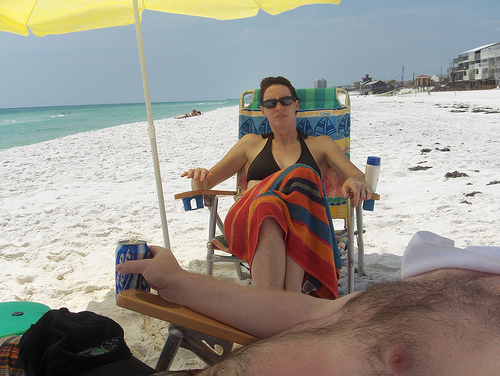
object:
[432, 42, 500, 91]
beach house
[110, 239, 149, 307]
can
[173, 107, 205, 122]
people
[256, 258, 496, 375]
chest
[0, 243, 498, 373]
man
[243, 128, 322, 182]
top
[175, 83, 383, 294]
beach chair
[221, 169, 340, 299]
towel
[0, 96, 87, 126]
water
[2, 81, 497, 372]
sand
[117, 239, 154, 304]
beer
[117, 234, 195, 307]
hand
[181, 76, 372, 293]
lady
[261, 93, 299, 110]
glasses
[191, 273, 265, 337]
arm rest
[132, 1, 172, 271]
pole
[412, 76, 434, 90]
building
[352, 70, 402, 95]
building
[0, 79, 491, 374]
beach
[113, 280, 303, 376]
chair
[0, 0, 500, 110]
background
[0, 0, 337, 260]
umbrella